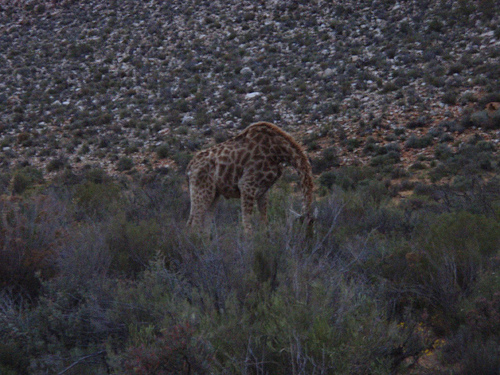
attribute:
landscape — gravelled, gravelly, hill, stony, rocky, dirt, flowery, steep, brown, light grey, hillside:
[0, 1, 500, 198]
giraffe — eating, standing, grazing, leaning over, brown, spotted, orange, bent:
[181, 119, 319, 242]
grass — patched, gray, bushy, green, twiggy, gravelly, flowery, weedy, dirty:
[1, 154, 499, 375]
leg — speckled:
[239, 193, 256, 235]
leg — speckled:
[256, 193, 271, 232]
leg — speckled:
[185, 181, 217, 234]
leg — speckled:
[200, 191, 221, 242]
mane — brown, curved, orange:
[245, 120, 314, 208]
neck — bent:
[274, 130, 316, 211]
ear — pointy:
[288, 208, 301, 223]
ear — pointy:
[305, 205, 317, 223]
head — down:
[288, 208, 320, 257]